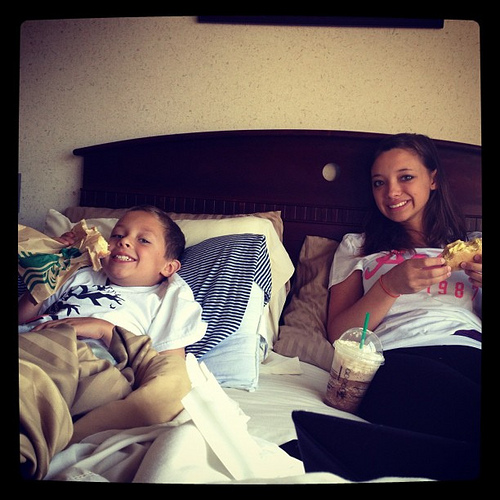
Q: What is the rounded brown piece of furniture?
A: A headboard.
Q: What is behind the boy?
A: A blue and white striped pillow.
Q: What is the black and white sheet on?
A: A pillow.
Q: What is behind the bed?
A: A headboard.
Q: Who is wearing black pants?
A: The woman.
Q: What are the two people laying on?
A: The bed.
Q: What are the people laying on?
A: A bed.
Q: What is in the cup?
A: A straw.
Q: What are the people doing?
A: Eating.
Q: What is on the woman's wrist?
A: A bracelet.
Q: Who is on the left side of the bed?
A: The boy.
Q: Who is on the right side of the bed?
A: The girl.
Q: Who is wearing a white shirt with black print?
A: The boy.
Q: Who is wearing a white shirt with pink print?
A: The girl.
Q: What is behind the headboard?
A: The wall.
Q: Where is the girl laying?
A: On th bed.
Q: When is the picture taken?
A: Night time.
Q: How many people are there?
A: 2.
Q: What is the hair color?
A: Blonde.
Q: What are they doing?
A: Eating.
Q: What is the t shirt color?
A: White.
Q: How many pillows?
A: 4.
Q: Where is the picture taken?
A: In a bedroom.